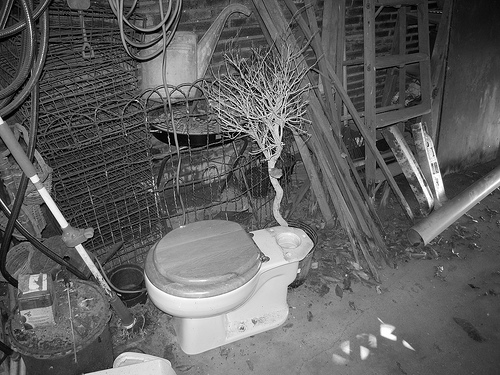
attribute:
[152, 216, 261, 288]
lid — wooden 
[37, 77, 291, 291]
fencing — pile, metal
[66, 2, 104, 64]
shovel — little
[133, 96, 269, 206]
grill —  old black 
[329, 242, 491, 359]
leaves — Dry 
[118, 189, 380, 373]
toilet — seat , wooden 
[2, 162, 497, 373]
floor — dirty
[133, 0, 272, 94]
wall — brick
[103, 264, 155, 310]
flower pot — Black plastic flower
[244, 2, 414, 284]
posts — stack 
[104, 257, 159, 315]
plant pot — small black plant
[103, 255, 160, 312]
pot — empty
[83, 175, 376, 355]
toilet — white, discarded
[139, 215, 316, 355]
toilet — lid , worth salvaging, abandoned, very nice, wood lid, broken, outdoors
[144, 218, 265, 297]
lid — closed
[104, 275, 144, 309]
bucket — empty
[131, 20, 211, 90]
can — covered, old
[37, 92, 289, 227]
fence — Wire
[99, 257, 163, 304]
pot — empty black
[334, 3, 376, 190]
wooden ladder — Wooden 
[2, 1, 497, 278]
brick wall — brick 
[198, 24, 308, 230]
leafless tree — small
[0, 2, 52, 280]
hose — garden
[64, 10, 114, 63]
shovel — small, hanging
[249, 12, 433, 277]
ladder — metal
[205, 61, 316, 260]
trees — baby 